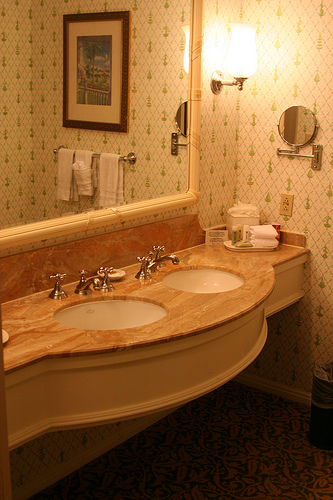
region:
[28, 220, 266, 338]
there are two sinks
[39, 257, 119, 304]
the handles are metal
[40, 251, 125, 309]
the handles are silver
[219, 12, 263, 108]
the light is on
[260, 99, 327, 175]
the mirror is on the wall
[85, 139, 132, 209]
the towel is white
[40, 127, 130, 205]
there are many towels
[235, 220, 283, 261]
the towels are folded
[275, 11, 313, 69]
the wallpaper is decorated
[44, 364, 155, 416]
the base is white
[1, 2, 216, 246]
There's a mirror over the counter.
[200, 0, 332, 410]
There is wallpaper on the wall.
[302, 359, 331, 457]
The trash can has a bag in it.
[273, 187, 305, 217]
There's a plug in outlet on wall.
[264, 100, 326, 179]
There's a mirror on the wall.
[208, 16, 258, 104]
There's a light beside the mirror.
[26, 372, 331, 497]
The floor is carpeted.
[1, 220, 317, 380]
The counter has two sink bowls.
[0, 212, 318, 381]
Countertop and backsplash ia marbled.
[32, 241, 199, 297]
The faucets are silvertone.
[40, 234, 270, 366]
two sinks side by side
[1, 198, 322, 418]
pink marble counter top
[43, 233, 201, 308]
four silver sink knobs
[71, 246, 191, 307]
two silver faucets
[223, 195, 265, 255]
white box of white klenexes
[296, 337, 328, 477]
trash can on the floor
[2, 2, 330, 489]
diamond patterned wall paper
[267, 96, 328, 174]
fold out mirror on the wall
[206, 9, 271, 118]
lamp on the wall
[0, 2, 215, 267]
huge white framed mirror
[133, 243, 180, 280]
a silver, metal faucet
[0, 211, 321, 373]
a marble sink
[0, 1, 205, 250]
a large clear mirror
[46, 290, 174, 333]
a white porcelain sink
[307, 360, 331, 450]
a black trash can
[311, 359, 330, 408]
a clear bag in a trash can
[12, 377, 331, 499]
a carpet with leaves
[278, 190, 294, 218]
a light fixture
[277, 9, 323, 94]
green and white wall paper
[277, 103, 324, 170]
round mirror attached to wall.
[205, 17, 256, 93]
Wall lamp hanging on the wall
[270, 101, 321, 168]
Wall mirror hanging on the wall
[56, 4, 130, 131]
Framed picture hanging on the wall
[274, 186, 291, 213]
Electrical outlet on the wall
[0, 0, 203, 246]
Large framed mirror on the wall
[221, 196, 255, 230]
White tissue box with tissue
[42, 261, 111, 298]
Silver faucets on the sink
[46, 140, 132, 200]
Silver towel rack hanging on the wall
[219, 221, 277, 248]
White container with lotions and white towels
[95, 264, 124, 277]
White soap dish sitting on vanity